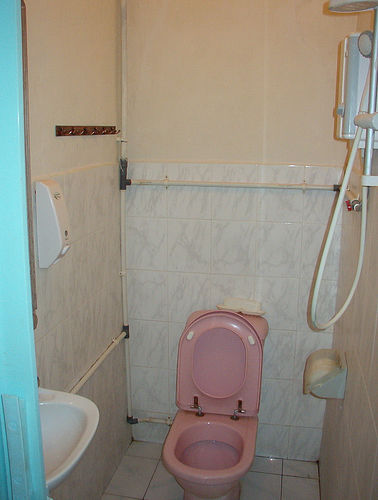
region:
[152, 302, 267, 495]
The comode is pink in color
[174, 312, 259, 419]
The comode seat is turned up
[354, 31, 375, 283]
There is a shower head off to the right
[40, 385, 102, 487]
The sink is white in color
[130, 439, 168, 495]
White tile on the floor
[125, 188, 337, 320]
The wall is a white and light grey tile.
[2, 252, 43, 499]
Light blue door to the left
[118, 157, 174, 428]
Plumbing pipes are on the outside of the wall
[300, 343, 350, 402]
Toliet paper holder is on the right of the comode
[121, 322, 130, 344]
Black connectors in the plumbing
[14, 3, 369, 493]
a bathroom with a pink toilet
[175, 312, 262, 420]
the seat is up on the toilet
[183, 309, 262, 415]
the lid is up on the toilet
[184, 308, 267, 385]
the water tank on the toilet is pink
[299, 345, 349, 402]
the toilet paper holder is ceramic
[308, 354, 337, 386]
a roll of white toilet paper is in the holder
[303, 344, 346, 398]
a plastic cover is over the toilet paper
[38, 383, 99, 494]
a white ceramic sink is in the bathroom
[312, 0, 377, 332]
a shower head is on the wall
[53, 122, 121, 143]
a rack with hooks is on the wall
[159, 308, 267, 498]
a pink toilet seat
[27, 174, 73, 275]
a soap dispenser over the sink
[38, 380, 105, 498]
the sink is white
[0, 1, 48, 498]
the door opens in front of the sink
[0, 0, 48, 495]
the door is blue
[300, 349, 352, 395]
a covered tp holder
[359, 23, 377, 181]
a shower head on the wall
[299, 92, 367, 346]
the cord of the shower head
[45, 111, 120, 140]
coat hooks on the wall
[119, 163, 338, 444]
the wall is tiled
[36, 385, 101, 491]
bathroom sink for washing hands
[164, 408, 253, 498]
toilet bowl to dispose of human fecal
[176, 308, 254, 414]
toilet seat to sit on for comfort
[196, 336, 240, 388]
toilet lid to put down when finished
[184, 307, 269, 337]
tank filled with water to aid in the flushing of fecal matter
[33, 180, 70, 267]
soap dispenser to aid in hand washing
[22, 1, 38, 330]
mirror to look at yourself while hand washing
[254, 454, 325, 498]
tile floors are easier to manage/clean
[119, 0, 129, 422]
pipes to aid in plumbing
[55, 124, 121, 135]
hanger for towels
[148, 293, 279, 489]
the toilet is pink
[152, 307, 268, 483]
the toilet seat is up